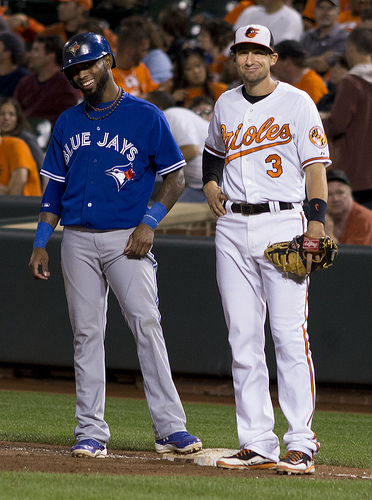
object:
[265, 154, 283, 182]
3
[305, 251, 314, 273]
finger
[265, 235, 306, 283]
mitt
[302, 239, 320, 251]
red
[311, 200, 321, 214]
nike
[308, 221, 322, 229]
wrist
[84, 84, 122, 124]
necklace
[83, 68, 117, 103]
neck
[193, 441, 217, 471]
base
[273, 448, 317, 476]
shoes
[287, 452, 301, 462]
laces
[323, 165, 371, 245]
fan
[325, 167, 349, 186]
hat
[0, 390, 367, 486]
grass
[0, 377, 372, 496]
field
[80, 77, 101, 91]
smiling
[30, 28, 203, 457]
ballplayer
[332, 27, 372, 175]
man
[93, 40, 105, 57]
blue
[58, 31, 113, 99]
head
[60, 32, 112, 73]
helmet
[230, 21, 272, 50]
hat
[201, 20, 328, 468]
player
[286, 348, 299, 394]
white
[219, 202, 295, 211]
belt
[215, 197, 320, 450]
pants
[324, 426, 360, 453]
green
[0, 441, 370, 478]
ground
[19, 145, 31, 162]
brown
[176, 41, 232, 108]
spectators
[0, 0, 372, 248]
stands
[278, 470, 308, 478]
spikes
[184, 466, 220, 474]
dirt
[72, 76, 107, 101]
beard